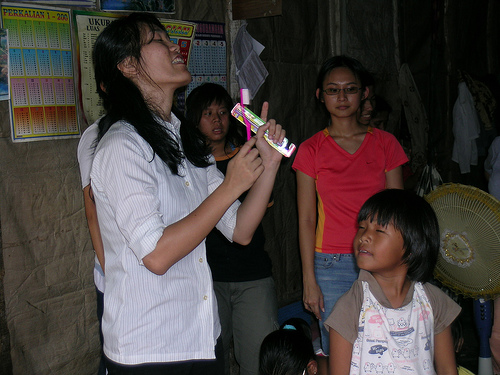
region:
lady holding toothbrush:
[44, 13, 309, 369]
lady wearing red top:
[232, 41, 443, 338]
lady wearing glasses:
[316, 60, 385, 123]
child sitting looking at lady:
[318, 172, 462, 373]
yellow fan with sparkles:
[378, 152, 498, 307]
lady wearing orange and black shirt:
[163, 76, 291, 356]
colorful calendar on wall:
[0, 0, 101, 172]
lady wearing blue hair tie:
[258, 307, 343, 373]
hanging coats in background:
[382, 40, 498, 211]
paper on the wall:
[222, 12, 303, 171]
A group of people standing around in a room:
[81, 16, 471, 373]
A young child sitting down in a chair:
[330, 185, 472, 373]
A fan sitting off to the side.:
[422, 185, 499, 370]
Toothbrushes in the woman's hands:
[225, 86, 297, 175]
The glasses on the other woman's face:
[320, 85, 362, 95]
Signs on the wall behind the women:
[0, 3, 265, 141]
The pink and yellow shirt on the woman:
[283, 124, 405, 256]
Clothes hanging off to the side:
[453, 76, 496, 180]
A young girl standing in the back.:
[186, 89, 301, 374]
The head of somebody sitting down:
[261, 311, 314, 372]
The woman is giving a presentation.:
[70, 15, 298, 362]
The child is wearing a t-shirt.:
[315, 190, 470, 370]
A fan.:
[420, 180, 497, 297]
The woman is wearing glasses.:
[310, 55, 365, 125]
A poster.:
[0, 7, 90, 137]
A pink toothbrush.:
[230, 76, 255, 171]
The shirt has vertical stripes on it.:
[75, 97, 245, 359]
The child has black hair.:
[346, 185, 448, 287]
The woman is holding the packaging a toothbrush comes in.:
[227, 97, 297, 154]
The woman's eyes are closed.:
[106, 11, 201, 107]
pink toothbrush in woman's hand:
[223, 83, 265, 140]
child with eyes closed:
[353, 214, 407, 241]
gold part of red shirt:
[303, 182, 333, 262]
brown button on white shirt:
[194, 290, 219, 308]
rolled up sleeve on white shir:
[113, 197, 180, 265]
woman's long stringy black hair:
[90, 17, 217, 182]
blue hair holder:
[272, 317, 313, 333]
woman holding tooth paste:
[229, 102, 299, 161]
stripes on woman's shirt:
[145, 287, 202, 332]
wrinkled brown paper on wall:
[25, 206, 85, 285]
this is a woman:
[95, 12, 190, 369]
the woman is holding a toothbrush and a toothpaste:
[230, 95, 285, 196]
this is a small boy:
[330, 195, 440, 374]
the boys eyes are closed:
[351, 220, 388, 236]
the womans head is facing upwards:
[104, 13, 171, 117]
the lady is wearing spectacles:
[322, 85, 365, 95]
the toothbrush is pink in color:
[237, 89, 252, 137]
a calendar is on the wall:
[13, 14, 68, 139]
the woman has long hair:
[103, 100, 153, 136]